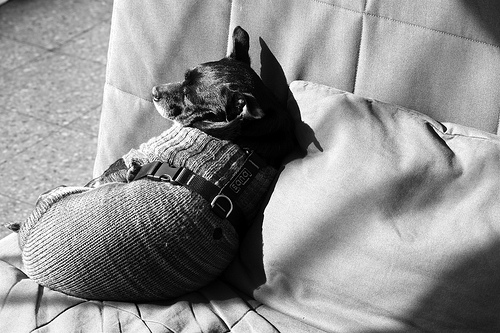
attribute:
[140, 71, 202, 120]
nose — little, black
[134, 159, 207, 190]
harness clasp — plastic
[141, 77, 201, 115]
nose — little, black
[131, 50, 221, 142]
nose — black , Small 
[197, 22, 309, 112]
ear — black 